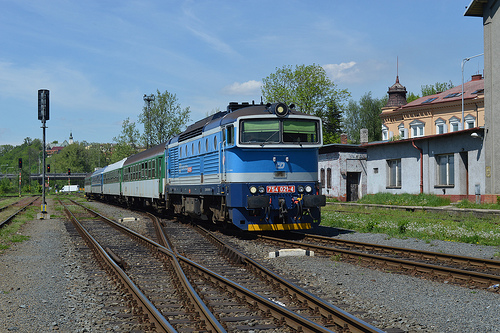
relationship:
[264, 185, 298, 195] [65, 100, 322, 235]
red license on train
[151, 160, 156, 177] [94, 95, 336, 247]
window on train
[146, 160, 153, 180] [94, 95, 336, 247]
window on train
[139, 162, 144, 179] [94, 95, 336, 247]
window on train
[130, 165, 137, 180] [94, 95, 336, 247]
window on train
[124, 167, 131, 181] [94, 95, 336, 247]
window on train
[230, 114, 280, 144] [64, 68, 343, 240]
window on train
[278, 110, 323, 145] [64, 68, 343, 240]
window on train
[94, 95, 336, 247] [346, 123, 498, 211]
train near building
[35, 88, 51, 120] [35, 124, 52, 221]
light on pole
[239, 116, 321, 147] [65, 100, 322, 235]
front window on train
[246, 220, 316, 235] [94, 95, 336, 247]
trim on train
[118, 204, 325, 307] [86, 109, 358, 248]
tracks by train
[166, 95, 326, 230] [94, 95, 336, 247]
blue engine on train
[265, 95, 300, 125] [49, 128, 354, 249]
head light on train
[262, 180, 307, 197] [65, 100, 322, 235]
letters on front of train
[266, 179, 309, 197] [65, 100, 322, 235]
numbers on front of train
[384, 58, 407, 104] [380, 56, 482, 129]
tower on building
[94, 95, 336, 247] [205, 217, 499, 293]
train on tracks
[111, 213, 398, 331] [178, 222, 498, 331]
gravel on tracks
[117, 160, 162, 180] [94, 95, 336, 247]
windows on train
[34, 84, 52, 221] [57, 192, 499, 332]
light by tracks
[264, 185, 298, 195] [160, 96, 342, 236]
red license on train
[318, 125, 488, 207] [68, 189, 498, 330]
building by train tracks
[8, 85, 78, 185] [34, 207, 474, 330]
lights by tracks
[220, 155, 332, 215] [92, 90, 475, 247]
lights on front of train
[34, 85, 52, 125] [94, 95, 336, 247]
signal for train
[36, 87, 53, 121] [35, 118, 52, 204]
traffic light on pole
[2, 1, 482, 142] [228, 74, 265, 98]
sky with clouds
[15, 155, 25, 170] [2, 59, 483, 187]
traffic light standing in background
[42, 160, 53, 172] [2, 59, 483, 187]
traffic light standing in background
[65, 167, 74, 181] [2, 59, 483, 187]
traffic light standing in background